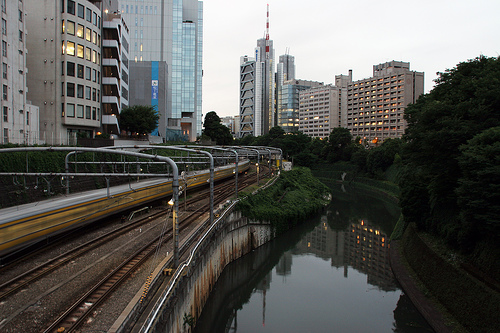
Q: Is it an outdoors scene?
A: Yes, it is outdoors.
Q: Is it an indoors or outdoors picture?
A: It is outdoors.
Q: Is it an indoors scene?
A: No, it is outdoors.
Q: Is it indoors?
A: No, it is outdoors.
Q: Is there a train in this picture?
A: Yes, there is a train.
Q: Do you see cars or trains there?
A: Yes, there is a train.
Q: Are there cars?
A: No, there are no cars.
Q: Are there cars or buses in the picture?
A: No, there are no cars or buses.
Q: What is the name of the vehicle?
A: The vehicle is a train.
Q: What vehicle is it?
A: The vehicle is a train.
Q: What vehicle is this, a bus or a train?
A: That is a train.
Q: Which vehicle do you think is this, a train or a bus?
A: That is a train.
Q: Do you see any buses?
A: No, there are no buses.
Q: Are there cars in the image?
A: No, there are no cars.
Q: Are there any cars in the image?
A: No, there are no cars.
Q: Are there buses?
A: No, there are no buses.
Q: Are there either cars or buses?
A: No, there are no buses or cars.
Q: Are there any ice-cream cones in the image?
A: No, there are no ice-cream cones.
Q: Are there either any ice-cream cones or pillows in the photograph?
A: No, there are no ice-cream cones or pillows.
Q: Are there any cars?
A: No, there are no cars.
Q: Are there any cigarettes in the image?
A: No, there are no cigarettes.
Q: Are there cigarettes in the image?
A: No, there are no cigarettes.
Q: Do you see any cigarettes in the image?
A: No, there are no cigarettes.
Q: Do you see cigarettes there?
A: No, there are no cigarettes.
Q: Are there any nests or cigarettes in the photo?
A: No, there are no cigarettes or nests.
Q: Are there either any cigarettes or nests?
A: No, there are no cigarettes or nests.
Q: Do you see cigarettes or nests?
A: No, there are no cigarettes or nests.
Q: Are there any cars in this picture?
A: No, there are no cars.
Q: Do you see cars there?
A: No, there are no cars.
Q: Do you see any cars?
A: No, there are no cars.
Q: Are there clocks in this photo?
A: No, there are no clocks.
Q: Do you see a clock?
A: No, there are no clocks.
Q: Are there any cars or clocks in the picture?
A: No, there are no clocks or cars.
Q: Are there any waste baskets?
A: No, there are no waste baskets.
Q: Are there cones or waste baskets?
A: No, there are no waste baskets or cones.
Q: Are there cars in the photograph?
A: No, there are no cars.